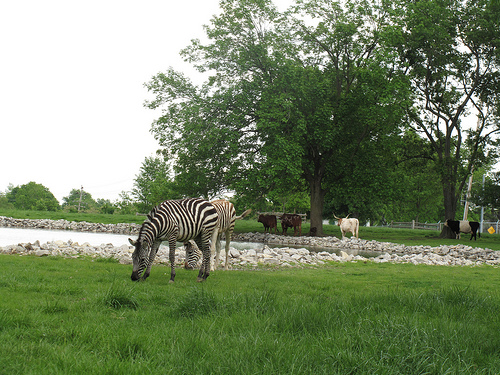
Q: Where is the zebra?
A: Outside on the grass.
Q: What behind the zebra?
A: Rocks.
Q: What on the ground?
A: Grass.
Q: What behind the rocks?
A: Big tree.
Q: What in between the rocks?
A: Water.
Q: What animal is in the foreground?
A: Zebra.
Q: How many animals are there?
A: Six.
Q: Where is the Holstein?
A: Next to the fence.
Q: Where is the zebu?
A: Next to the pond.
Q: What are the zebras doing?
A: Eating grass.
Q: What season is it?
A: Summer.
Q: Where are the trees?
A: Among the cows.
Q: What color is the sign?
A: Yellow.